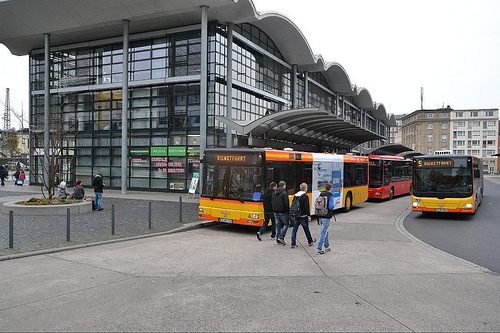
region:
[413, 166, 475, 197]
bus windshield is tinted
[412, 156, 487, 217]
bus is next to bus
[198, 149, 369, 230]
bus is next to bus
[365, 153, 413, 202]
bus is next to bus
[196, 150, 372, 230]
bubs in front of bus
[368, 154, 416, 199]
passenger bus is red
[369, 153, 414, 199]
bus behind other bus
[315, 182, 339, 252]
person carrying backpack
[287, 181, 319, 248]
person with black and white hoodie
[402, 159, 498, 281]
bus on paved road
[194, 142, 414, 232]
two buses parked by a curb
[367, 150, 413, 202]
a red city bus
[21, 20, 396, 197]
walls of building are glass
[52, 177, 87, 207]
two people having a seat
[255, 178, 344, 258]
four people walking together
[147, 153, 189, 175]
advertisment written on the sign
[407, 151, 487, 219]
a bus with its head lights on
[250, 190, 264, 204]
a blue piece of paper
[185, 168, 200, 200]
a street sign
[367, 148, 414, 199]
a bus with dark tinted windows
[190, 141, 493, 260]
several city buses at a bus stop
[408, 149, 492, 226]
an orange city bus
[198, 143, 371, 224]
an orange city bus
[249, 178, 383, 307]
four people walking across a sidewalk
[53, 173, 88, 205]
two people sitting on a concrete planter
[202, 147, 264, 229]
the front of a bus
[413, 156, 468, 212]
the front of a bus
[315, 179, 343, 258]
a man wearing jeans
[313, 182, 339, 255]
a man wearing a backpack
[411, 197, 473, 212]
the headlights on a bus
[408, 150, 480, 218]
orange and yellow bus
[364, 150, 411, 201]
red bus parked on the sidewalk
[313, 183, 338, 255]
person wearing a backpack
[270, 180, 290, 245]
person wearing a black coat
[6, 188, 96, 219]
concrete plant bed with flowers and a tree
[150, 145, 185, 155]
green sign in the window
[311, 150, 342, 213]
advertisement on side of the bus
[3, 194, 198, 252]
metal posts in the ground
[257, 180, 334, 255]
group of people walking on the sidewalk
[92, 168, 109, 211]
person standing in the courtyard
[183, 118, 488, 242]
Bus is in motion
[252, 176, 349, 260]
People are walking around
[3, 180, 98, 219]
This is a circle here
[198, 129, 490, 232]
Buses are yellow and black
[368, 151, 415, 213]
These buses are red and black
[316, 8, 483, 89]
The sky is cloudy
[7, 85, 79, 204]
Tree is bare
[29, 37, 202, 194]
Reflections on the wall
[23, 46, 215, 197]
Building made of glass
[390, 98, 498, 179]
Buildings behind the buses